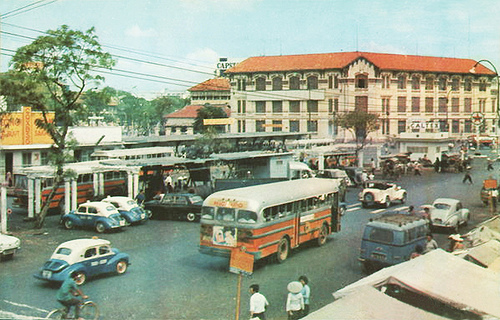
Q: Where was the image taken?
A: It was taken at the street.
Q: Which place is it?
A: It is a street.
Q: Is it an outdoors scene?
A: Yes, it is outdoors.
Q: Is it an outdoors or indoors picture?
A: It is outdoors.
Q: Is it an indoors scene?
A: No, it is outdoors.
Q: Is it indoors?
A: No, it is outdoors.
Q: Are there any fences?
A: No, there are no fences.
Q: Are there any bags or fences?
A: No, there are no fences or bags.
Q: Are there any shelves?
A: No, there are no shelves.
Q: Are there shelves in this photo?
A: No, there are no shelves.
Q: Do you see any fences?
A: No, there are no fences.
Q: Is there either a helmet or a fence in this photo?
A: No, there are no fences or helmets.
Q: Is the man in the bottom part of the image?
A: Yes, the man is in the bottom of the image.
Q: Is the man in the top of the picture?
A: No, the man is in the bottom of the image.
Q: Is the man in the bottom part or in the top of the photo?
A: The man is in the bottom of the image.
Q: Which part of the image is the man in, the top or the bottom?
A: The man is in the bottom of the image.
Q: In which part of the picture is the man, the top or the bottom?
A: The man is in the bottom of the image.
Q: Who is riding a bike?
A: The man is riding a bike.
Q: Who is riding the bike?
A: The man is riding a bike.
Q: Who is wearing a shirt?
A: The man is wearing a shirt.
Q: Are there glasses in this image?
A: No, there are no glasses.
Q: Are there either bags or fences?
A: No, there are no fences or bags.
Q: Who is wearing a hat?
A: The people are wearing a hat.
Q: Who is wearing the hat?
A: The people are wearing a hat.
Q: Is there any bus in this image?
A: Yes, there is a bus.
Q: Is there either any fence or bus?
A: Yes, there is a bus.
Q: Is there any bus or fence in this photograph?
A: Yes, there is a bus.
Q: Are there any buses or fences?
A: Yes, there is a bus.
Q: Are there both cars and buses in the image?
A: Yes, there are both a bus and a car.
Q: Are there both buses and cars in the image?
A: Yes, there are both a bus and a car.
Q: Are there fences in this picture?
A: No, there are no fences.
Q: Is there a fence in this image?
A: No, there are no fences.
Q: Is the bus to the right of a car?
A: Yes, the bus is to the right of a car.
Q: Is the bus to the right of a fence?
A: No, the bus is to the right of a car.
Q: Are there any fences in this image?
A: No, there are no fences.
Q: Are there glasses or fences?
A: No, there are no fences or glasses.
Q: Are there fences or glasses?
A: No, there are no fences or glasses.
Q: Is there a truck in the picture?
A: No, there are no trucks.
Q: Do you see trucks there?
A: No, there are no trucks.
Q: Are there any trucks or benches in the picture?
A: No, there are no trucks or benches.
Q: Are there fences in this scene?
A: No, there are no fences.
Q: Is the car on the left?
A: Yes, the car is on the left of the image.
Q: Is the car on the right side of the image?
A: No, the car is on the left of the image.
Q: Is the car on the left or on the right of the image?
A: The car is on the left of the image.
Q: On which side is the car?
A: The car is on the left of the image.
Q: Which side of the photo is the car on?
A: The car is on the left of the image.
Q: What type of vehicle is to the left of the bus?
A: The vehicle is a car.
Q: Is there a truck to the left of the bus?
A: No, there is a car to the left of the bus.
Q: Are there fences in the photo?
A: No, there are no fences.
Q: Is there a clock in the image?
A: No, there are no clocks.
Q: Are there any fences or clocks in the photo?
A: No, there are no clocks or fences.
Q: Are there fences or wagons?
A: No, there are no fences or wagons.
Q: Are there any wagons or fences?
A: No, there are no fences or wagons.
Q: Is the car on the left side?
A: Yes, the car is on the left of the image.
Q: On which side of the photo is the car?
A: The car is on the left of the image.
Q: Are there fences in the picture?
A: No, there are no fences.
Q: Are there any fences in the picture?
A: No, there are no fences.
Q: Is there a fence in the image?
A: No, there are no fences.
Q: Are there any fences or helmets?
A: No, there are no fences or helmets.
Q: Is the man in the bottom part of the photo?
A: Yes, the man is in the bottom of the image.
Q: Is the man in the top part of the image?
A: No, the man is in the bottom of the image.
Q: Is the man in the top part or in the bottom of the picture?
A: The man is in the bottom of the image.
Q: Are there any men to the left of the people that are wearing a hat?
A: Yes, there is a man to the left of the people.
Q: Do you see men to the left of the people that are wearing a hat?
A: Yes, there is a man to the left of the people.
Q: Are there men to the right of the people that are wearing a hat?
A: No, the man is to the left of the people.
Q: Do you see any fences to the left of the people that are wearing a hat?
A: No, there is a man to the left of the people.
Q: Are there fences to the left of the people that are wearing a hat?
A: No, there is a man to the left of the people.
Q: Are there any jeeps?
A: No, there are no jeeps.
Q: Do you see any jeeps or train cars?
A: No, there are no jeeps or train cars.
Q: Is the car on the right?
A: No, the car is on the left of the image.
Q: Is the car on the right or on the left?
A: The car is on the left of the image.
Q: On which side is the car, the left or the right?
A: The car is on the left of the image.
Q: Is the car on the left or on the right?
A: The car is on the left of the image.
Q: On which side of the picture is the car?
A: The car is on the left of the image.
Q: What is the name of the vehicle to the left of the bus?
A: The vehicle is a car.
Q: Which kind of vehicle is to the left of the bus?
A: The vehicle is a car.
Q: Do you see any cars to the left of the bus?
A: Yes, there is a car to the left of the bus.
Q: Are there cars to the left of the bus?
A: Yes, there is a car to the left of the bus.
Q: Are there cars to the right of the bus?
A: No, the car is to the left of the bus.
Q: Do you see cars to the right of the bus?
A: No, the car is to the left of the bus.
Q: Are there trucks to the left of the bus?
A: No, there is a car to the left of the bus.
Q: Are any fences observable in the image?
A: No, there are no fences.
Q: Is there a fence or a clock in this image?
A: No, there are no fences or clocks.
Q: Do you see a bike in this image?
A: Yes, there is a bike.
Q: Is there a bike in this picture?
A: Yes, there is a bike.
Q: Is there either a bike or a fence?
A: Yes, there is a bike.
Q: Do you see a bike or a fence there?
A: Yes, there is a bike.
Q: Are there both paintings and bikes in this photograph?
A: No, there is a bike but no paintings.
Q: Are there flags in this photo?
A: No, there are no flags.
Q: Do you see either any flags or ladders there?
A: No, there are no flags or ladders.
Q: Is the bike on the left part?
A: Yes, the bike is on the left of the image.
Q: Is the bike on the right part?
A: No, the bike is on the left of the image.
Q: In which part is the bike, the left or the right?
A: The bike is on the left of the image.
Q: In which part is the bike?
A: The bike is on the left of the image.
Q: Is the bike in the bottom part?
A: Yes, the bike is in the bottom of the image.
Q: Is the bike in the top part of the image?
A: No, the bike is in the bottom of the image.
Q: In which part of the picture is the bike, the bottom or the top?
A: The bike is in the bottom of the image.